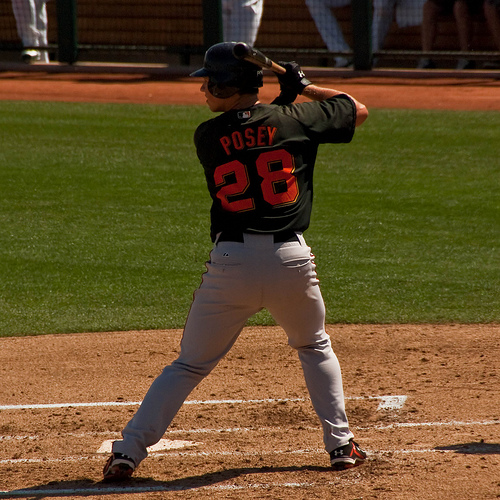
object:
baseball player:
[102, 42, 368, 483]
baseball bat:
[233, 42, 285, 74]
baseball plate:
[97, 439, 203, 454]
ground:
[1, 60, 499, 500]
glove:
[273, 62, 312, 95]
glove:
[271, 74, 297, 104]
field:
[0, 97, 499, 500]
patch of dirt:
[1, 312, 499, 499]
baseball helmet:
[190, 42, 263, 98]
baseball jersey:
[193, 93, 356, 235]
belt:
[217, 234, 305, 243]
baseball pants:
[110, 232, 350, 466]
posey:
[219, 126, 277, 155]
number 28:
[214, 149, 300, 213]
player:
[12, 1, 50, 62]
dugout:
[0, 0, 500, 73]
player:
[222, 0, 264, 48]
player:
[308, 3, 385, 66]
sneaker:
[103, 450, 137, 480]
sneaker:
[327, 439, 366, 467]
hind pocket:
[281, 259, 310, 270]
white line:
[0, 394, 407, 410]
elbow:
[351, 102, 369, 126]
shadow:
[0, 465, 333, 500]